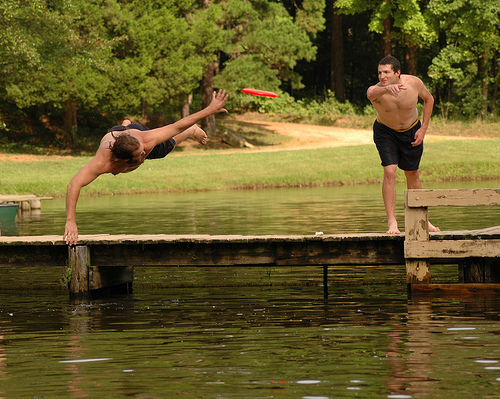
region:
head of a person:
[373, 42, 405, 83]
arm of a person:
[358, 65, 410, 106]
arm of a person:
[154, 102, 224, 161]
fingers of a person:
[208, 87, 234, 102]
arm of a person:
[40, 152, 117, 262]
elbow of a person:
[57, 178, 86, 198]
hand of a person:
[60, 210, 102, 246]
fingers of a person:
[60, 232, 85, 247]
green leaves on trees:
[2, 2, 499, 142]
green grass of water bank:
[2, 140, 499, 195]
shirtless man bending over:
[369, 56, 436, 234]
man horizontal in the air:
[63, 87, 230, 243]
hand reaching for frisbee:
[209, 85, 277, 115]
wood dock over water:
[0, 231, 497, 297]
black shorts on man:
[374, 120, 423, 168]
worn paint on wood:
[408, 188, 498, 208]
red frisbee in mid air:
[240, 85, 275, 97]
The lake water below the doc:
[71, 308, 451, 385]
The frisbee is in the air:
[236, 80, 282, 101]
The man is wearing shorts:
[365, 115, 429, 175]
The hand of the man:
[383, 79, 411, 101]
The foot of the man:
[378, 214, 405, 238]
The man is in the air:
[47, 73, 242, 253]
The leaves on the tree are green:
[9, 8, 271, 82]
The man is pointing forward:
[365, 48, 452, 238]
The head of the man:
[103, 121, 154, 166]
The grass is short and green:
[216, 149, 355, 180]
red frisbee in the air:
[241, 84, 278, 100]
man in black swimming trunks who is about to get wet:
[61, 87, 231, 248]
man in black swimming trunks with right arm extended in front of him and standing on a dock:
[366, 54, 445, 234]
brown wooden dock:
[1, 226, 498, 301]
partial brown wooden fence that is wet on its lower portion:
[401, 187, 496, 298]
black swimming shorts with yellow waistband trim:
[370, 115, 426, 173]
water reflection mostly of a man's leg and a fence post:
[386, 298, 438, 395]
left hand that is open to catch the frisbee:
[208, 86, 280, 115]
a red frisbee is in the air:
[243, 85, 276, 99]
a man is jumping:
[59, 87, 230, 246]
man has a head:
[105, 132, 145, 165]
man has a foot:
[188, 124, 206, 144]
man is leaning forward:
[367, 54, 439, 231]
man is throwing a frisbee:
[235, 56, 440, 232]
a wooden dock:
[2, 186, 498, 289]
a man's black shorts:
[372, 118, 425, 171]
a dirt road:
[237, 113, 375, 150]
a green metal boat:
[0, 203, 21, 221]